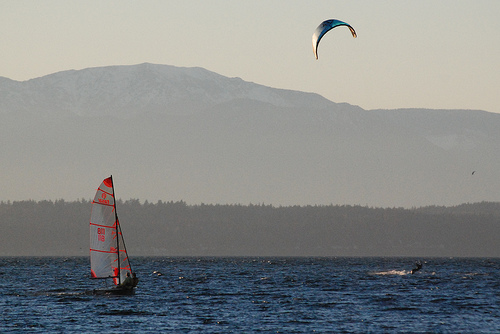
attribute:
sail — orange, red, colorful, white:
[88, 175, 135, 287]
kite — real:
[313, 19, 357, 61]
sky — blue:
[2, 2, 312, 62]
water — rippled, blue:
[1, 295, 499, 333]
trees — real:
[128, 194, 499, 258]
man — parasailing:
[411, 262, 425, 274]